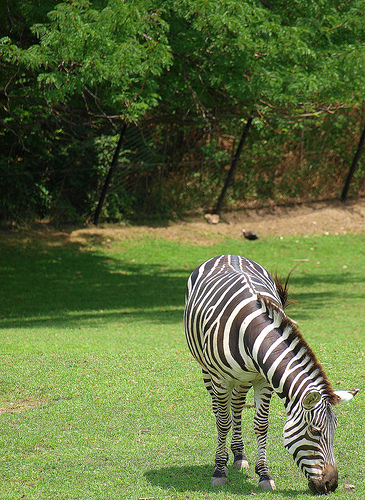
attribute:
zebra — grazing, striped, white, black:
[182, 255, 359, 492]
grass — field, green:
[1, 212, 363, 499]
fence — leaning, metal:
[3, 108, 363, 232]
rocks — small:
[206, 207, 263, 243]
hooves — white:
[205, 453, 280, 493]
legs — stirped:
[197, 366, 277, 497]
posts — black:
[92, 117, 257, 233]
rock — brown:
[241, 221, 255, 244]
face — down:
[300, 402, 339, 487]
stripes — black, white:
[187, 256, 322, 397]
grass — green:
[3, 233, 359, 487]